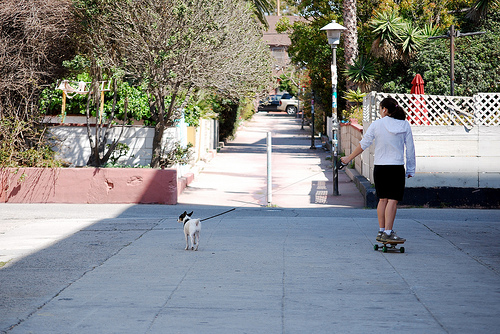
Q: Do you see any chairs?
A: No, there are no chairs.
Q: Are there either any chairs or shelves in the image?
A: No, there are no chairs or shelves.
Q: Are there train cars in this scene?
A: No, there are no train cars.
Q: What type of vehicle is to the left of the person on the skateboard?
A: The vehicle is a car.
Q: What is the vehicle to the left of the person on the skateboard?
A: The vehicle is a car.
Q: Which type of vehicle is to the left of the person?
A: The vehicle is a car.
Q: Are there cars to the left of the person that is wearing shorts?
A: Yes, there is a car to the left of the person.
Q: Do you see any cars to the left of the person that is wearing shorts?
A: Yes, there is a car to the left of the person.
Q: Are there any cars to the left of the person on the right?
A: Yes, there is a car to the left of the person.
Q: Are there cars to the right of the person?
A: No, the car is to the left of the person.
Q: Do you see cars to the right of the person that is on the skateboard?
A: No, the car is to the left of the person.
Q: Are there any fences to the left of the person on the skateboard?
A: No, there is a car to the left of the person.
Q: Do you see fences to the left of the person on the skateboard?
A: No, there is a car to the left of the person.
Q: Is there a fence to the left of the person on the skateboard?
A: No, there is a car to the left of the person.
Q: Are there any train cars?
A: No, there are no train cars.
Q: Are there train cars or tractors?
A: No, there are no train cars or tractors.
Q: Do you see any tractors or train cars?
A: No, there are no train cars or tractors.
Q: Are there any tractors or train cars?
A: No, there are no train cars or tractors.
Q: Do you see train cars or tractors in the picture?
A: No, there are no train cars or tractors.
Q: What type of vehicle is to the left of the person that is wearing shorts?
A: The vehicle is a car.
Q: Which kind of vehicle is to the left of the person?
A: The vehicle is a car.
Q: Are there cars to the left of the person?
A: Yes, there is a car to the left of the person.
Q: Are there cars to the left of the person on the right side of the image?
A: Yes, there is a car to the left of the person.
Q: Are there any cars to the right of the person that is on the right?
A: No, the car is to the left of the person.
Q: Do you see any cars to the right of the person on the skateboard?
A: No, the car is to the left of the person.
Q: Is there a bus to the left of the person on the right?
A: No, there is a car to the left of the person.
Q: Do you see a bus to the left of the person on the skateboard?
A: No, there is a car to the left of the person.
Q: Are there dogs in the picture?
A: Yes, there is a dog.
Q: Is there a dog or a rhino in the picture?
A: Yes, there is a dog.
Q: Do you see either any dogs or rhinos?
A: Yes, there is a dog.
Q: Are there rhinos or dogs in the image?
A: Yes, there is a dog.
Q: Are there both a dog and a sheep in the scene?
A: No, there is a dog but no sheep.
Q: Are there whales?
A: No, there are no whales.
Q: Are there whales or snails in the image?
A: No, there are no whales or snails.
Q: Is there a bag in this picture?
A: No, there are no bags.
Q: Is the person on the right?
A: Yes, the person is on the right of the image.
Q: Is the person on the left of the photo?
A: No, the person is on the right of the image.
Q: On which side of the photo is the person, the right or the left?
A: The person is on the right of the image.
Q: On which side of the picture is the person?
A: The person is on the right of the image.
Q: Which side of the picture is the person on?
A: The person is on the right of the image.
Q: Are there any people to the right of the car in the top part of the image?
A: Yes, there is a person to the right of the car.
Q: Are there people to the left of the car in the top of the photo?
A: No, the person is to the right of the car.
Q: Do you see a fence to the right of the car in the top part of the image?
A: No, there is a person to the right of the car.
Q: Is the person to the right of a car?
A: Yes, the person is to the right of a car.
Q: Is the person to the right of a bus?
A: No, the person is to the right of a car.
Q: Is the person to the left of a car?
A: No, the person is to the right of a car.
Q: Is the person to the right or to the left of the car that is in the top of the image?
A: The person is to the right of the car.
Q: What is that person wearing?
A: The person is wearing shorts.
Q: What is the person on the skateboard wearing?
A: The person is wearing shorts.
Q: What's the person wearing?
A: The person is wearing shorts.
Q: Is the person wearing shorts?
A: Yes, the person is wearing shorts.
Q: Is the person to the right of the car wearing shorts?
A: Yes, the person is wearing shorts.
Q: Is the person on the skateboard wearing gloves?
A: No, the person is wearing shorts.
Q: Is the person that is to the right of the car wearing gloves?
A: No, the person is wearing shorts.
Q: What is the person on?
A: The person is on the skateboard.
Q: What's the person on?
A: The person is on the skateboard.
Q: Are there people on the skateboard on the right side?
A: Yes, there is a person on the skateboard.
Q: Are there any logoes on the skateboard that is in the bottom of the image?
A: No, there is a person on the skateboard.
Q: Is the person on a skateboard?
A: Yes, the person is on a skateboard.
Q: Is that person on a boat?
A: No, the person is on a skateboard.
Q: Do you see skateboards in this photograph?
A: Yes, there is a skateboard.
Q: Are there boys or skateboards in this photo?
A: Yes, there is a skateboard.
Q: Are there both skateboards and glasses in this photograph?
A: No, there is a skateboard but no glasses.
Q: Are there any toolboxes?
A: No, there are no toolboxes.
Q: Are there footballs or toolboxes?
A: No, there are no toolboxes or footballs.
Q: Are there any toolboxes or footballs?
A: No, there are no toolboxes or footballs.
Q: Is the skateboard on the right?
A: Yes, the skateboard is on the right of the image.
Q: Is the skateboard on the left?
A: No, the skateboard is on the right of the image.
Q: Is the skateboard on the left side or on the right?
A: The skateboard is on the right of the image.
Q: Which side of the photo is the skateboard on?
A: The skateboard is on the right of the image.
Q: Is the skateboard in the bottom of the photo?
A: Yes, the skateboard is in the bottom of the image.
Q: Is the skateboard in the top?
A: No, the skateboard is in the bottom of the image.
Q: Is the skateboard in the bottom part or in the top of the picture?
A: The skateboard is in the bottom of the image.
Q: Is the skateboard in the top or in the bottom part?
A: The skateboard is in the bottom of the image.